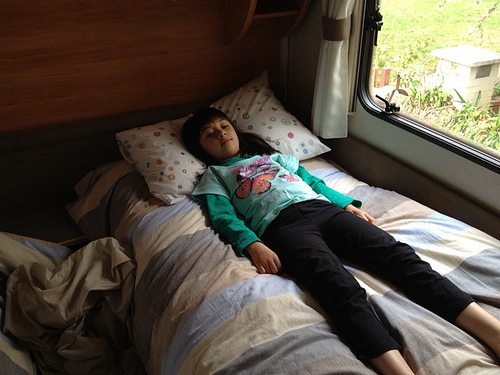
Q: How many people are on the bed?
A: One.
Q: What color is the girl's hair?
A: Black.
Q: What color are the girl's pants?
A: Black.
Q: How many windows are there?
A: One.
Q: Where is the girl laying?
A: The bed.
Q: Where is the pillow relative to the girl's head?
A: Beneath it.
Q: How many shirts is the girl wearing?
A: Two.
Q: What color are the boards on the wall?
A: Brown.